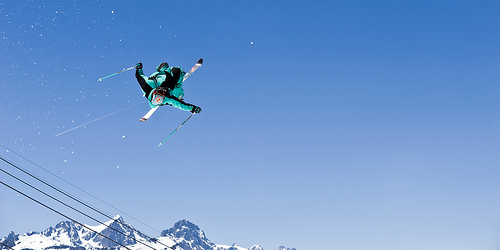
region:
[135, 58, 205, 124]
A person on skis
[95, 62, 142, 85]
A ski pole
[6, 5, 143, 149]
Bits of snow flying into the air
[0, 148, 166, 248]
Black cables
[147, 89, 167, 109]
The helmet of the skier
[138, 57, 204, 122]
A single ski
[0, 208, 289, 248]
Jagged snow-covered mountains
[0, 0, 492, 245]
A clear blue sky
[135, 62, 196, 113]
A light blue and black snow suit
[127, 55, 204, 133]
A skier upside down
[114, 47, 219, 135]
a skier is making a flip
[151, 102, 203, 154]
a pole in right hand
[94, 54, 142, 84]
a pole on left hand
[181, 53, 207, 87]
ski with black tip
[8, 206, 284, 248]
mountains cover with snow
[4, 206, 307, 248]
the mountains are rocky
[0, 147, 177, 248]
power poles are black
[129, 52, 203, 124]
skier wears a green and black suit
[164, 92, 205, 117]
cat is lying on a purple fabric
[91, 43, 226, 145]
skiier in the air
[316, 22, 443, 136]
blue sky in the distance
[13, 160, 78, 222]
wires to a ski lift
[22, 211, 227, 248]
mountains in the distance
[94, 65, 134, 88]
ski pole in man's hand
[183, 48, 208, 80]
ski used by a man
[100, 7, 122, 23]
snow scattered in the sky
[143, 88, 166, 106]
helmet on man's head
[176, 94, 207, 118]
right arm of a man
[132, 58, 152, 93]
left arm of a man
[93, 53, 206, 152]
Skier in the midair.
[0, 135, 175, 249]
Power lines in the air.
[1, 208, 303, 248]
Mountains in the forefront.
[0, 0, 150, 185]
Snow in the air.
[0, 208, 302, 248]
Snow on the mountain.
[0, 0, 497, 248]
blue sky in the background.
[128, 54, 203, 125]
Aqua outfit on the skier.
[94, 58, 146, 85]
Ski poles in the hand.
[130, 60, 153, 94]
black stripe on the outfit.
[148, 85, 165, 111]
Hat on the skier.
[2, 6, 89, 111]
Small flecks of snow in the sky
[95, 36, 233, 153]
The skier in blue is upside down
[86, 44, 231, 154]
A skier performing a huge jump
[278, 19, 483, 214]
A clear blue sky behind the skier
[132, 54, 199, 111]
The suit of the skier is light blue and black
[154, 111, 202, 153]
A thin ski pole in the man's hand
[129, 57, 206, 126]
A white ski on the man's feet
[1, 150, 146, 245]
Black power lines beneath the skier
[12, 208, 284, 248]
A large mountain range in the background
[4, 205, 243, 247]
Snow covering the mountains